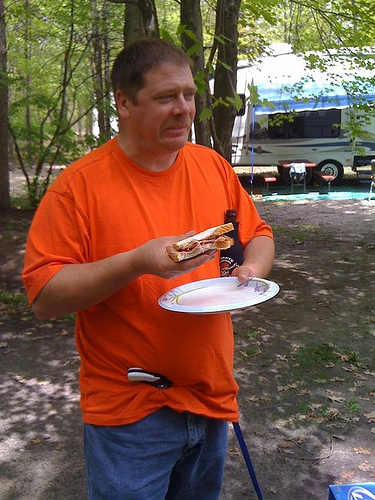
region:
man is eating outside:
[115, 36, 275, 473]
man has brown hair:
[114, 26, 192, 119]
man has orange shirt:
[27, 137, 237, 355]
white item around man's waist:
[116, 346, 184, 395]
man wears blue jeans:
[100, 403, 247, 477]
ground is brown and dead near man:
[241, 238, 330, 468]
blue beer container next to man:
[311, 472, 371, 496]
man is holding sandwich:
[155, 209, 271, 298]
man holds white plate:
[161, 237, 281, 335]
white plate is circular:
[168, 249, 311, 334]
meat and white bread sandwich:
[165, 218, 240, 271]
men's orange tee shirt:
[26, 125, 276, 458]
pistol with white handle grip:
[110, 354, 178, 412]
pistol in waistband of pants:
[116, 345, 189, 410]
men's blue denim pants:
[69, 366, 265, 498]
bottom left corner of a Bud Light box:
[320, 473, 373, 499]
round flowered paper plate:
[156, 266, 290, 330]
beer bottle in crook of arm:
[213, 205, 247, 276]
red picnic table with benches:
[257, 154, 339, 206]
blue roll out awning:
[245, 77, 374, 118]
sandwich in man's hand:
[166, 219, 236, 266]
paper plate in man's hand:
[150, 277, 289, 319]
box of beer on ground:
[321, 470, 373, 498]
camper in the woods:
[241, 32, 373, 203]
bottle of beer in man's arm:
[211, 200, 249, 294]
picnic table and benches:
[260, 159, 341, 189]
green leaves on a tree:
[14, 8, 82, 92]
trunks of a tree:
[180, 5, 244, 119]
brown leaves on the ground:
[306, 400, 335, 420]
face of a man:
[104, 35, 215, 155]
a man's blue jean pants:
[78, 410, 226, 496]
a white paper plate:
[155, 268, 278, 310]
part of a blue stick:
[229, 418, 267, 496]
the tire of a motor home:
[318, 159, 340, 180]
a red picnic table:
[257, 165, 335, 193]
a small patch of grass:
[287, 337, 354, 367]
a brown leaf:
[350, 443, 368, 454]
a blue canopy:
[244, 85, 372, 188]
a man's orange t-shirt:
[22, 149, 275, 425]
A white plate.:
[152, 255, 307, 330]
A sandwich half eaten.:
[157, 205, 253, 271]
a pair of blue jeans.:
[78, 395, 240, 498]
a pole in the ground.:
[228, 405, 263, 497]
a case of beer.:
[316, 459, 371, 498]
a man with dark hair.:
[101, 10, 213, 169]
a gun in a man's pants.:
[112, 339, 197, 403]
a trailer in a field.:
[193, 46, 374, 191]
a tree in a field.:
[178, 0, 255, 179]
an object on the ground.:
[316, 439, 372, 498]